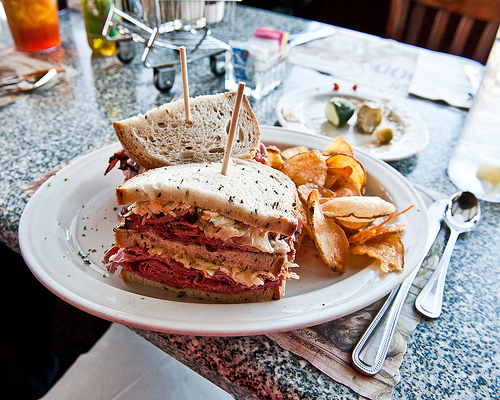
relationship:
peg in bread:
[219, 81, 246, 173] [115, 154, 306, 237]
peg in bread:
[176, 46, 192, 123] [113, 88, 261, 168]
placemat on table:
[268, 184, 448, 399] [0, 4, 499, 399]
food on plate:
[326, 96, 393, 146] [276, 85, 430, 162]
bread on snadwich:
[115, 154, 306, 237] [103, 154, 308, 303]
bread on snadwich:
[113, 227, 286, 275] [103, 154, 308, 303]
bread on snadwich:
[121, 267, 277, 302] [103, 154, 308, 303]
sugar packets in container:
[225, 26, 290, 91] [223, 54, 291, 99]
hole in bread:
[154, 121, 173, 131] [113, 88, 261, 168]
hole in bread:
[168, 120, 179, 130] [113, 88, 261, 168]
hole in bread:
[178, 150, 197, 160] [113, 88, 261, 168]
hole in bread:
[206, 144, 226, 156] [113, 88, 261, 168]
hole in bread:
[235, 126, 248, 144] [113, 88, 261, 168]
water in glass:
[449, 66, 497, 203] [445, 25, 498, 203]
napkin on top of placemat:
[407, 48, 481, 109] [285, 20, 484, 113]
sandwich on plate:
[106, 90, 262, 180] [18, 125, 433, 338]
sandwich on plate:
[101, 156, 307, 304] [18, 125, 433, 338]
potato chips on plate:
[266, 136, 408, 277] [18, 125, 433, 338]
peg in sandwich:
[176, 46, 192, 123] [106, 90, 262, 180]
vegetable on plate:
[325, 97, 355, 127] [276, 85, 430, 162]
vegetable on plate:
[357, 100, 386, 131] [276, 85, 430, 162]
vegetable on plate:
[373, 126, 393, 147] [276, 85, 430, 162]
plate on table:
[47, 93, 396, 340] [82, 20, 418, 350]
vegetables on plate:
[193, 98, 403, 243] [14, 64, 424, 340]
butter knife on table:
[350, 197, 450, 377] [38, 18, 389, 292]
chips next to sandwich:
[257, 141, 406, 274] [111, 86, 303, 303]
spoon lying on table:
[413, 189, 482, 319] [0, 4, 499, 399]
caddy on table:
[223, 43, 289, 102] [0, 4, 499, 399]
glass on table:
[445, 25, 498, 203] [0, 4, 499, 399]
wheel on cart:
[153, 62, 176, 93] [104, 7, 231, 94]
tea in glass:
[0, 0, 60, 53] [3, 0, 66, 71]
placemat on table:
[284, 17, 423, 97] [0, 4, 499, 399]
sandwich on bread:
[101, 156, 307, 304] [115, 154, 305, 236]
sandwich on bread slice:
[101, 156, 307, 304] [111, 222, 289, 275]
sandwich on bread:
[101, 156, 307, 304] [121, 270, 286, 302]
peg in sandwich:
[219, 81, 246, 173] [101, 156, 307, 304]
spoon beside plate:
[413, 189, 482, 319] [18, 125, 433, 338]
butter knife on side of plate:
[350, 197, 450, 377] [18, 125, 433, 338]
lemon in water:
[476, 163, 498, 185] [443, 24, 499, 203]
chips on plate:
[257, 141, 406, 274] [18, 125, 433, 338]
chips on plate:
[257, 133, 413, 282] [18, 125, 433, 338]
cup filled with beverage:
[0, 0, 61, 52] [22, 9, 54, 35]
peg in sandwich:
[176, 46, 192, 123] [111, 86, 303, 303]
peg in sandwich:
[176, 46, 192, 123] [95, 74, 259, 168]